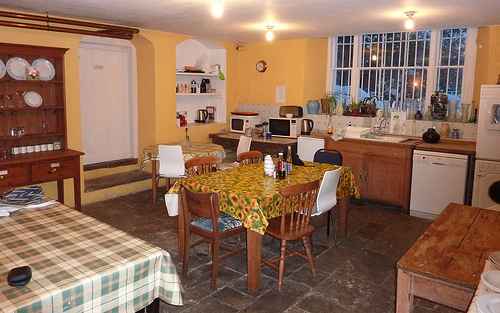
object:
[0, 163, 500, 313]
ground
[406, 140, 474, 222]
washer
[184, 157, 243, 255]
chair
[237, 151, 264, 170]
chair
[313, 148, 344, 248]
chair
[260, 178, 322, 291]
chair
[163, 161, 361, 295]
table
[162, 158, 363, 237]
table cloth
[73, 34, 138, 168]
door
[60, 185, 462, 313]
floor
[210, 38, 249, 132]
corner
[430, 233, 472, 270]
wood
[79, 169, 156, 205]
step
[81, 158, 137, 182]
step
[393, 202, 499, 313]
table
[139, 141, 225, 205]
table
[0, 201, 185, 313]
table clothe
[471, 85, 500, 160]
washer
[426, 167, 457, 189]
white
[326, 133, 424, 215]
cabinet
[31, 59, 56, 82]
plate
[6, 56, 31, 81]
plate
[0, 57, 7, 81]
plate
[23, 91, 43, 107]
plate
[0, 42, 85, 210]
shelf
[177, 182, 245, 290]
chair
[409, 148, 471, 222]
dishwasher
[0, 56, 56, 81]
china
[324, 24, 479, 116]
window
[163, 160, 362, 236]
cloth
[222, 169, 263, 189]
flowers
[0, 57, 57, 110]
utensils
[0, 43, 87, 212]
cabinet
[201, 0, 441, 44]
lights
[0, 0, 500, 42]
ceiling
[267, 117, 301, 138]
microwave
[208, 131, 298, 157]
table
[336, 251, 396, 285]
tile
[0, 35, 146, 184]
doorway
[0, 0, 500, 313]
kitchen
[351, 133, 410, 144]
sink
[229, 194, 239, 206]
flower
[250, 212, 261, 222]
flower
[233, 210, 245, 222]
flower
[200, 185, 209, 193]
flower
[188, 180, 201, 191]
flower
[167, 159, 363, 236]
sunflowers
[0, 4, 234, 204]
wall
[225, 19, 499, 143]
wall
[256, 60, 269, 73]
clock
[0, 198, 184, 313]
table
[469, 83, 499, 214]
dryer